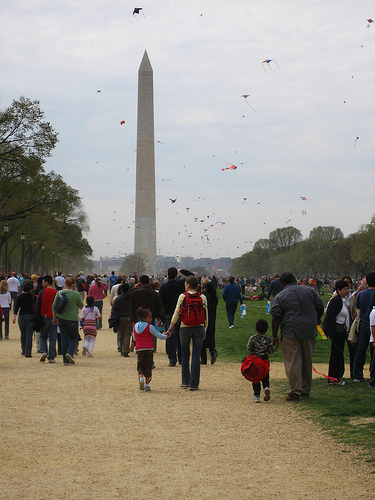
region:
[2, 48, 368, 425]
people moving towards a large monument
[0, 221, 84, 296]
row of lights on tall black poles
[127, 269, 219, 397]
woman and little girl holding hands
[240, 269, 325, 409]
man and little boy holding hands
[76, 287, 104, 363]
young girl running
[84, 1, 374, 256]
kites of varying shapes and sizes in the air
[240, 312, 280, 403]
boy carrying a red backpack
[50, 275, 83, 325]
woman wearing a green top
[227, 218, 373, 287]
trees of varying heights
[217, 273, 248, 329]
person dressed in blue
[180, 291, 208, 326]
woman's backpack is red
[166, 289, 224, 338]
woman's shirt is yellow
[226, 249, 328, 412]
man holding little boy's hand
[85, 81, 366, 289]
kites flying in sky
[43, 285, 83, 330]
woman's shirt is red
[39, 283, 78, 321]
woman carrying a bag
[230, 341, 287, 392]
little boy holding red backpack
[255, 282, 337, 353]
man's shirt is gray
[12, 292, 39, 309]
woman's shirt is black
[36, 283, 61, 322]
man's shirt is red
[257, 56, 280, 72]
a small colorful kite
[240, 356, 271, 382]
a dark red backpack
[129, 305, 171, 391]
a little girl in red and blue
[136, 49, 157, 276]
a tall gray tower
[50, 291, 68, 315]
a big blue purse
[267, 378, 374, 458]
a small patch of green grass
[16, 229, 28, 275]
a tall black light post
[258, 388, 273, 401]
the shoe of a little boy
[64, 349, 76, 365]
the shoe of a woman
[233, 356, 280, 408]
red and black back pack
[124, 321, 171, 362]
blue hoodie and red vest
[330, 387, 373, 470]
green grass with dirt patch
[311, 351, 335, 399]
red tail of a kite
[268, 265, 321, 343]
person wearing a gray shirt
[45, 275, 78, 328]
person wearing a green shirt and black purse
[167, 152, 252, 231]
kites flying in the sky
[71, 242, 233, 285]
mist over peoples heads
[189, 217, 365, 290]
green leaves on trees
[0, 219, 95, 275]
line of black poles with lights on them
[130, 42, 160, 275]
the Washington monument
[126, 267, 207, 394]
a mother hold a child's hand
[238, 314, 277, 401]
a child with a red backpack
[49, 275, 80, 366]
a woman walking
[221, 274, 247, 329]
a man in blue walking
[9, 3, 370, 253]
a sky full of kites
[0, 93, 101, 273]
a row of green trees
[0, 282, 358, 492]
a dirt pathway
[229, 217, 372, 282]
a row of green trees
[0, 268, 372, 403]
a crowd of people